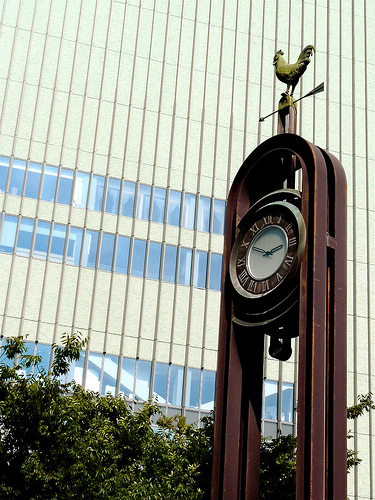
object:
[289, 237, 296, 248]
roman numeral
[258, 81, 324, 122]
arrow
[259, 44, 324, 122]
molded metal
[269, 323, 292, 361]
part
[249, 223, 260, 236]
numeral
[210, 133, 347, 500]
brown pillars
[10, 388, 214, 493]
tree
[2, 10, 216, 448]
building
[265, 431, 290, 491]
vane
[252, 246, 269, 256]
hand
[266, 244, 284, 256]
hand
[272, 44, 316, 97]
rooster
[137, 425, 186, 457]
wood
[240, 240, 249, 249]
ten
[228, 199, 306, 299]
clock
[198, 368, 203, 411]
edge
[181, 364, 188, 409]
edge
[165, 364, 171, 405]
edge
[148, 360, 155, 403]
edge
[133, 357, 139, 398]
edge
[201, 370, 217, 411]
window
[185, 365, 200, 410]
window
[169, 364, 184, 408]
window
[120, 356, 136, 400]
window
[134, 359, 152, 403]
window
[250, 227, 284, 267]
time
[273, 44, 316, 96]
chicken replica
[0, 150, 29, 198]
window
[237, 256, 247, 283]
numbers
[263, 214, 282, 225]
numbers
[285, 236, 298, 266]
numbers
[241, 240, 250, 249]
numeral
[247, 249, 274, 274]
interior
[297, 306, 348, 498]
pillar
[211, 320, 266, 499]
pillar